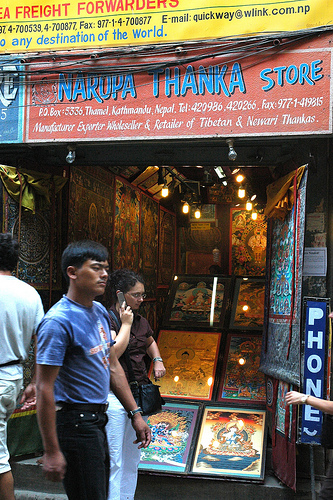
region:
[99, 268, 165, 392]
a woman holding the phone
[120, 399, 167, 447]
man wearing a watch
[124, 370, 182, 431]
the bag is black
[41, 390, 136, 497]
the pants are black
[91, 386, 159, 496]
woman's pants are white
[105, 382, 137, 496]
woman's pants are white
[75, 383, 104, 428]
man is wearing a belt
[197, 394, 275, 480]
painting of a buddha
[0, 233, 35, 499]
a man in a white shirt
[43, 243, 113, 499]
a man with black pants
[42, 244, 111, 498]
a man wearing a blue shirt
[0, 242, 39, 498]
a man wearing khaki shorts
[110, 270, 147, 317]
a woman on her cellphone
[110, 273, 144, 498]
a woman wearing white pants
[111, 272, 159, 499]
a woman wearing a maroon shirt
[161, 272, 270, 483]
6 art works for display in a store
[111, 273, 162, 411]
a woman using a black handbag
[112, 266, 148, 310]
a woman wearing glasses looking at art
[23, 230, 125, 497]
Man walking and wearing a blue t shirt with an image on the front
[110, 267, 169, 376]
A woman with black hair and glasses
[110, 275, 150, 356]
A woman in a button down shirt talking on her cell phone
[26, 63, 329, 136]
A large orange sign with big blue lettering and small white letters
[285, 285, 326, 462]
Up and down blue sign that says phone in white letters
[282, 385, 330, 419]
Person's forearm with a silver watch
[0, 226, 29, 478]
Man with black hair and a white shirt and white shorts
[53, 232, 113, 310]
Man with black hair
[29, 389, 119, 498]
Black pants being worn by a person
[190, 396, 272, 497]
Colorful painting with a black frame on display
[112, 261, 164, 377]
woman talking on a cellphone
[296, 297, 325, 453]
blue sign with white lettering saying "Phone"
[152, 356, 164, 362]
woman wearing a blue watch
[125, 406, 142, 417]
man wearing a blue watch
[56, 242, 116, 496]
man wearing black pants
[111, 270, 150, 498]
woman wearing white pants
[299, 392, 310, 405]
gold watch on an arm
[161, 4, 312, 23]
email address on a yellow sign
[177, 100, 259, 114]
telephone number on a red sign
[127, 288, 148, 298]
woman wearing glasses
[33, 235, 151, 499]
man walking next to art store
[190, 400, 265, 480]
piece of framed artwork for sale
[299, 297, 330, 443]
the word "phone" on a sign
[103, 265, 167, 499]
woman talking on a cellphone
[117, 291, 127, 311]
gray cellphone in the woman's hand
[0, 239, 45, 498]
man in white walking by the store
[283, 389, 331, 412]
person's arm reaching out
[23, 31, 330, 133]
banner with the name of the store on it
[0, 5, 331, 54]
yellow banner with contact information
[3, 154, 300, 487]
store full of artwork for sale